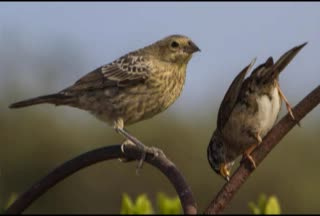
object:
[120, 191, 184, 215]
leaves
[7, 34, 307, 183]
birds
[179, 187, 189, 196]
white spot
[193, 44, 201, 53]
beak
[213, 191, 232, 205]
knob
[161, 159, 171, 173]
knob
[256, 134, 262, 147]
leg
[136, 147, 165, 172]
claw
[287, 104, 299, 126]
claw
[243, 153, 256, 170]
claw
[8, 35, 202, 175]
bird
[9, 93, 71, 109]
tail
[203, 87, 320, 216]
branch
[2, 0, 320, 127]
skies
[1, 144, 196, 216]
branch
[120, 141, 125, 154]
claw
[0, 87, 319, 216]
plant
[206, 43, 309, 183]
bird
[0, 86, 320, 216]
pole